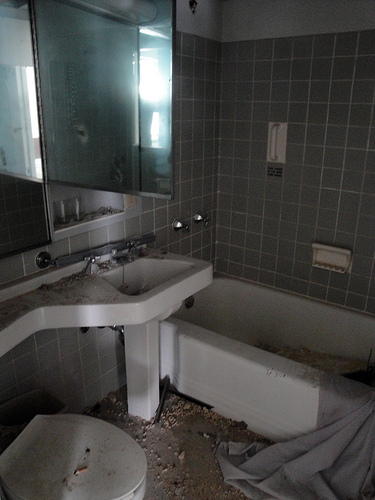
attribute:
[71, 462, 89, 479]
butt — old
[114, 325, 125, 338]
pipe — silver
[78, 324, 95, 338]
pipe — silver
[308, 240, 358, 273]
holder — white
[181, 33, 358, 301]
wall — tiled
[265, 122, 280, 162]
bar — white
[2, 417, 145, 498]
cover — closed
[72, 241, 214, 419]
sink — tall, white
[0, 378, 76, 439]
trash can — short, white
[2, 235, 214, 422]
sink — white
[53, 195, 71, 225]
glass cup — empty, dirty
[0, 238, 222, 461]
sink — dirty, white, tall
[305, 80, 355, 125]
ground — dirty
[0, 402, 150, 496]
seat — white, dirty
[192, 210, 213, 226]
knob — silver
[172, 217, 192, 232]
knob — silver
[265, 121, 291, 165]
grip — white, short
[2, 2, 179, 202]
mirror — open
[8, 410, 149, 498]
lid — closed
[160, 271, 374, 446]
tub — white, low, dirty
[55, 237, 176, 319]
sink — curved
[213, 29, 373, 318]
wall — gray, tiled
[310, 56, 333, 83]
tile — green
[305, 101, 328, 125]
tile — green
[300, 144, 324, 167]
tile — green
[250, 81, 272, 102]
tile — green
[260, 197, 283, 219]
tile — green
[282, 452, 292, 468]
cloth — white, dirty, old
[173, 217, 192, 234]
handle — metal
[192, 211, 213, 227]
handle — metal